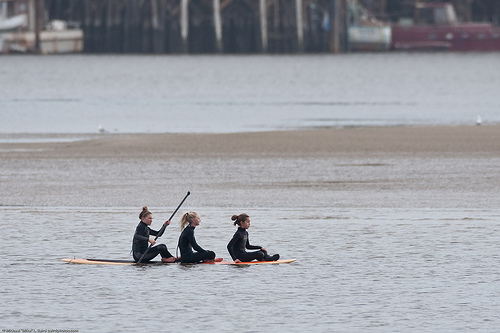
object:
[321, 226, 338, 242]
ground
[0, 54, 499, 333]
choppy water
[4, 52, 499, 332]
sea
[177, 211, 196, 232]
hair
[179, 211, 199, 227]
blonde hair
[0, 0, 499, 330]
outdoors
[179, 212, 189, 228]
ponytail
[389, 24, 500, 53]
boat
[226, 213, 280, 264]
girl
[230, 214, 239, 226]
pony tail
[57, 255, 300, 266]
board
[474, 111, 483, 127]
buoy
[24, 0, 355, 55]
pylons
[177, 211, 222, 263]
girl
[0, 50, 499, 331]
water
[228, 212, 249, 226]
hair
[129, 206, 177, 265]
girls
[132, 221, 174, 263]
wet suit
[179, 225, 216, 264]
wet suit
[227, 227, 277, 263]
wet suit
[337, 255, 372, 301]
part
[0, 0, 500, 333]
photo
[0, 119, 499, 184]
sand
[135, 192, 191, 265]
oar